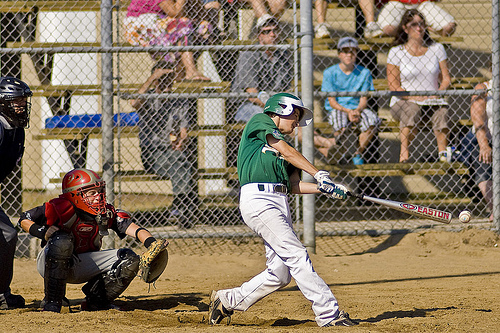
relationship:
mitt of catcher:
[136, 216, 173, 280] [4, 138, 196, 331]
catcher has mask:
[4, 138, 196, 331] [76, 179, 94, 211]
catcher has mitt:
[4, 138, 196, 331] [136, 216, 173, 280]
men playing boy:
[173, 81, 353, 326] [173, 81, 353, 326]